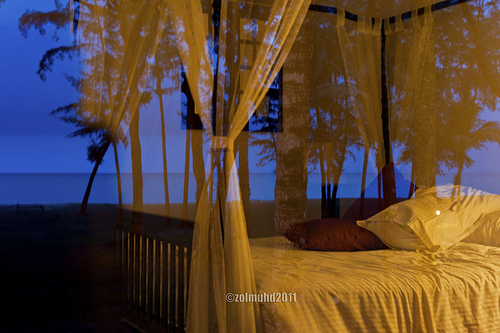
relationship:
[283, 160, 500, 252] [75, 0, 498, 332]
pillows on bed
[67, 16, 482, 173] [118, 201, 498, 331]
netting around bed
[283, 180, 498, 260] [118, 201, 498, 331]
pillows on bed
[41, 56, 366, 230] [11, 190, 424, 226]
trees on beach